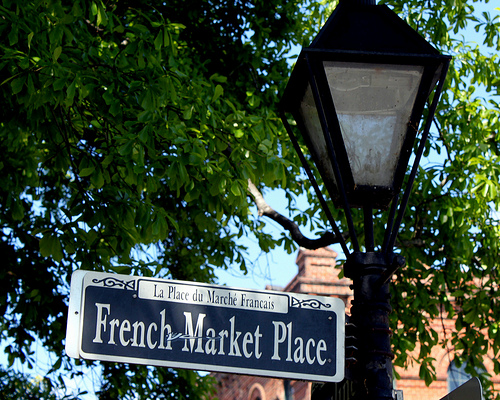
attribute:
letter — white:
[132, 320, 150, 352]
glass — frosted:
[309, 65, 450, 201]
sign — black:
[54, 249, 390, 382]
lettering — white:
[75, 281, 322, 371]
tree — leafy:
[69, 28, 305, 213]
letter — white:
[272, 318, 288, 369]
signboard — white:
[80, 271, 343, 383]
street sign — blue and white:
[80, 269, 344, 385]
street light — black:
[273, 0, 448, 398]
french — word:
[93, 297, 173, 355]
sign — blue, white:
[79, 273, 344, 382]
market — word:
[179, 311, 267, 359]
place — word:
[267, 321, 328, 364]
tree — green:
[4, 4, 485, 396]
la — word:
[152, 281, 164, 299]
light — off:
[272, 1, 454, 256]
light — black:
[274, 1, 453, 307]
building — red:
[194, 245, 484, 398]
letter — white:
[153, 304, 173, 351]